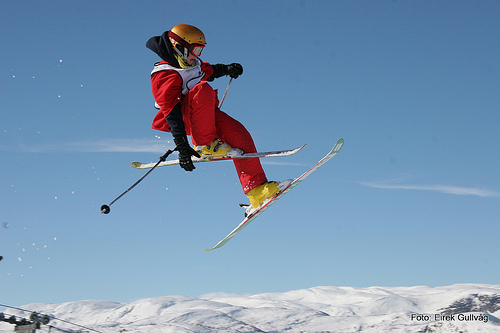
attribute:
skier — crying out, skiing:
[137, 17, 303, 215]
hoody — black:
[142, 31, 179, 74]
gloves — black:
[171, 63, 246, 172]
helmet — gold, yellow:
[167, 22, 213, 60]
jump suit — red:
[144, 56, 273, 196]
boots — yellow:
[195, 133, 289, 216]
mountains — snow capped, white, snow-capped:
[1, 281, 499, 332]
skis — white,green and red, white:
[125, 130, 353, 255]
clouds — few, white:
[346, 170, 493, 208]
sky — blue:
[3, 1, 497, 282]